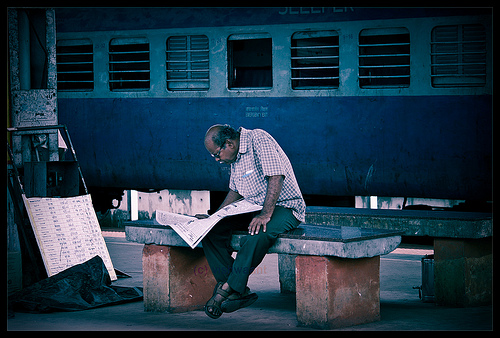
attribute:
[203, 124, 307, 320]
man — sitting, old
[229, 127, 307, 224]
shirt — checkered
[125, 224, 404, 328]
bench — concrete, old, red, black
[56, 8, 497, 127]
train — dirty, old, blue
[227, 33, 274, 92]
window — broken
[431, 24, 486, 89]
window — closed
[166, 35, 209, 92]
window — closed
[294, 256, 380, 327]
leg — brick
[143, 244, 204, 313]
leg — red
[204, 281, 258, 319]
sandals — brown, crossed